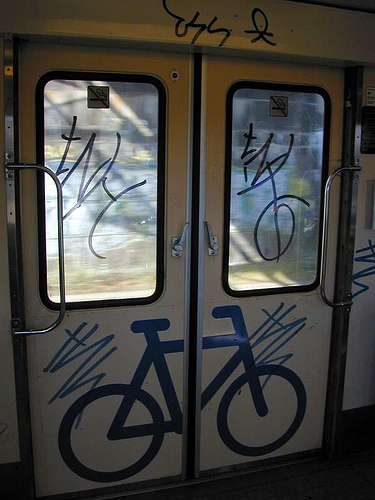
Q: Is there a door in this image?
A: Yes, there is a door.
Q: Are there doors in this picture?
A: Yes, there is a door.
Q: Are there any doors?
A: Yes, there is a door.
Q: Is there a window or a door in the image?
A: Yes, there is a door.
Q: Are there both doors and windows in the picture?
A: Yes, there are both a door and a window.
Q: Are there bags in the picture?
A: No, there are no bags.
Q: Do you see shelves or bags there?
A: No, there are no bags or shelves.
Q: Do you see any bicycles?
A: Yes, there is a bicycle.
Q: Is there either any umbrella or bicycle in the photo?
A: Yes, there is a bicycle.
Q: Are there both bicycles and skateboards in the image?
A: No, there is a bicycle but no skateboards.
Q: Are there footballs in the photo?
A: No, there are no footballs.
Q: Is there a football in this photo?
A: No, there are no footballs.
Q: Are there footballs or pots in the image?
A: No, there are no footballs or pots.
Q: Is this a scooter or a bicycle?
A: This is a bicycle.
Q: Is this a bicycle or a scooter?
A: This is a bicycle.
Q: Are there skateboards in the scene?
A: No, there are no skateboards.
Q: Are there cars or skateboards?
A: No, there are no skateboards or cars.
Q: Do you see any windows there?
A: Yes, there is a window.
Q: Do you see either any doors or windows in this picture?
A: Yes, there is a window.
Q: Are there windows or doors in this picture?
A: Yes, there is a window.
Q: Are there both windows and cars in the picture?
A: No, there is a window but no cars.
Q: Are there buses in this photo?
A: No, there are no buses.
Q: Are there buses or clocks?
A: No, there are no buses or clocks.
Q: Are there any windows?
A: Yes, there is a window.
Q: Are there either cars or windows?
A: Yes, there is a window.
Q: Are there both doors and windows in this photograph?
A: Yes, there are both a window and a door.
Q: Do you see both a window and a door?
A: Yes, there are both a window and a door.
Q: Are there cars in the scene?
A: No, there are no cars.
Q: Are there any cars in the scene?
A: No, there are no cars.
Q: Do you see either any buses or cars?
A: No, there are no cars or buses.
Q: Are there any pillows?
A: No, there are no pillows.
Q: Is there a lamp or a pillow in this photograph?
A: No, there are no pillows or lamps.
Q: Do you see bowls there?
A: No, there are no bowls.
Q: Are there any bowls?
A: No, there are no bowls.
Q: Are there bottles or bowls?
A: No, there are no bowls or bottles.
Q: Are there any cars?
A: No, there are no cars.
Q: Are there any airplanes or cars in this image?
A: No, there are no cars or airplanes.